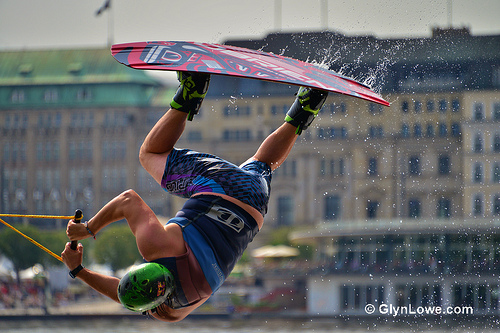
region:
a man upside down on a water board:
[48, 30, 398, 324]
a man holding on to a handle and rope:
[3, 183, 81, 300]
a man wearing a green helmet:
[125, 253, 171, 308]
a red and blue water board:
[70, 33, 366, 78]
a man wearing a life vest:
[150, 215, 225, 306]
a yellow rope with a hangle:
[9, 171, 96, 298]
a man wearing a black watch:
[65, 253, 98, 293]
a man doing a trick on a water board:
[66, 33, 379, 316]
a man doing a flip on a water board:
[37, 56, 424, 319]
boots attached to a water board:
[169, 73, 333, 123]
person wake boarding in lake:
[40, 32, 426, 311]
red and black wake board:
[104, 39, 391, 109]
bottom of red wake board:
[105, 39, 391, 105]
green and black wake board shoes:
[170, 69, 318, 131]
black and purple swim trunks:
[181, 145, 271, 218]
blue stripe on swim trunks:
[190, 174, 221, 197]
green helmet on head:
[118, 260, 170, 313]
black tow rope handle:
[66, 202, 83, 263]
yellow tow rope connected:
[0, 203, 69, 282]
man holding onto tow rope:
[48, 88, 318, 311]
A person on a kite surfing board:
[57, 71, 328, 321]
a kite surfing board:
[103, 39, 390, 110]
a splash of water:
[258, 10, 496, 331]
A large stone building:
[1, 47, 170, 228]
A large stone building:
[171, 36, 499, 227]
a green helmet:
[116, 257, 171, 317]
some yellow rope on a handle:
[0, 209, 84, 267]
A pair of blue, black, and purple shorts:
[158, 147, 272, 216]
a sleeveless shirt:
[156, 192, 258, 312]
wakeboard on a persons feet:
[122, 31, 387, 121]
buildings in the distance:
[344, 135, 491, 306]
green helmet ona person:
[110, 241, 171, 313]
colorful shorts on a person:
[165, 143, 263, 211]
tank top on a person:
[171, 185, 241, 309]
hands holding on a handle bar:
[54, 194, 98, 292]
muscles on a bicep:
[95, 174, 173, 266]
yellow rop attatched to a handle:
[8, 204, 78, 288]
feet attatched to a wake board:
[167, 64, 325, 132]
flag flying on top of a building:
[95, 3, 116, 54]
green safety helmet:
[108, 262, 188, 322]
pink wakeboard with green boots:
[106, 21, 412, 135]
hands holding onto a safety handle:
[9, 195, 103, 281]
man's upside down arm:
[61, 180, 192, 262]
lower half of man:
[107, 19, 412, 169]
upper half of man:
[4, 214, 289, 331]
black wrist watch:
[65, 261, 90, 278]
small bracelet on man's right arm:
[73, 211, 103, 242]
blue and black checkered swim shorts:
[146, 142, 282, 218]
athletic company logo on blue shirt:
[198, 194, 254, 236]